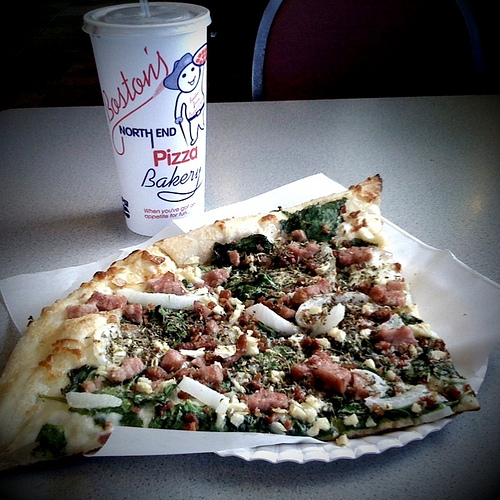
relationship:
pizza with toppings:
[28, 138, 414, 400] [203, 245, 345, 339]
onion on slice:
[173, 369, 227, 413] [28, 138, 414, 400]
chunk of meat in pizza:
[265, 356, 381, 389] [140, 161, 431, 414]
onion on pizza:
[173, 369, 227, 413] [28, 138, 414, 400]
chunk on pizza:
[116, 231, 423, 422] [28, 138, 414, 400]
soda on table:
[78, 11, 227, 229] [203, 78, 495, 173]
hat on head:
[154, 49, 188, 78] [169, 63, 209, 99]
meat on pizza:
[289, 326, 449, 397] [28, 138, 414, 400]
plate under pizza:
[0, 190, 449, 293] [28, 138, 414, 400]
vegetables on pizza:
[131, 307, 359, 332] [28, 138, 414, 400]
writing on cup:
[108, 121, 185, 149] [78, 11, 227, 229]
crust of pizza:
[25, 214, 227, 351] [28, 138, 414, 400]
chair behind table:
[251, 3, 491, 166] [203, 78, 495, 173]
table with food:
[203, 78, 495, 173] [28, 138, 414, 400]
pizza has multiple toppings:
[28, 138, 414, 400] [143, 261, 348, 358]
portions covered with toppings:
[95, 225, 436, 448] [150, 236, 375, 339]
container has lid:
[78, 11, 227, 229] [51, 1, 222, 46]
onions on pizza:
[119, 277, 300, 331] [28, 138, 414, 400]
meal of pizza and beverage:
[18, 11, 470, 338] [78, 11, 227, 229]